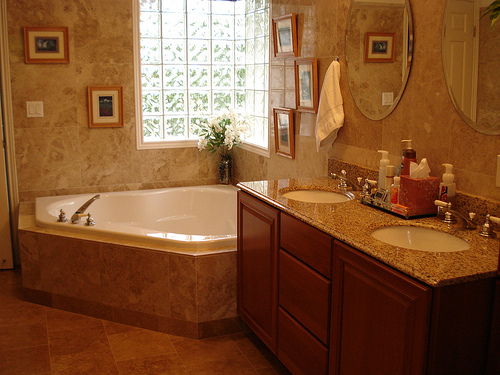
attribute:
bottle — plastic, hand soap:
[437, 156, 467, 206]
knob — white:
[432, 197, 454, 223]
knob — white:
[468, 207, 495, 237]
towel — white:
[308, 56, 373, 183]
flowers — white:
[190, 99, 255, 151]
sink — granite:
[241, 176, 494, 303]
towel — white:
[321, 64, 340, 139]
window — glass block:
[131, 0, 278, 155]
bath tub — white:
[30, 177, 238, 258]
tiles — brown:
[28, 311, 178, 373]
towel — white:
[312, 58, 344, 156]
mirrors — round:
[332, 5, 497, 133]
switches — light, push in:
[21, 98, 46, 122]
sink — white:
[277, 182, 357, 208]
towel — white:
[312, 60, 346, 152]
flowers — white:
[194, 106, 250, 152]